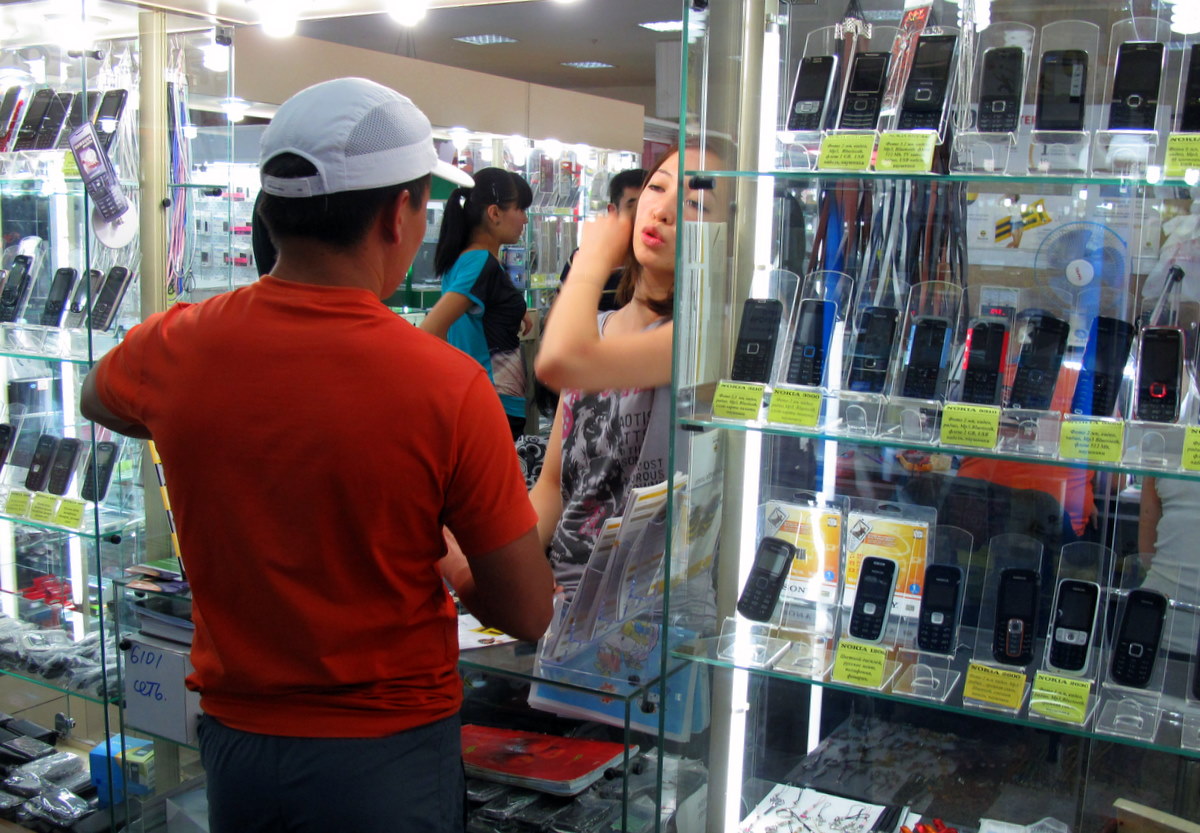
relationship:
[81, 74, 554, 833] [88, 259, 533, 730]
man wearing shirt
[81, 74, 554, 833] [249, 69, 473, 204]
man wearing hat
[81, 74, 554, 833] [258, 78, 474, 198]
man wearing cap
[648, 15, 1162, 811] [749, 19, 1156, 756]
case of phones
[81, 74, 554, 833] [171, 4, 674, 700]
man at window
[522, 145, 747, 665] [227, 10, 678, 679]
woman at window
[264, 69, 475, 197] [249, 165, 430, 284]
cap on head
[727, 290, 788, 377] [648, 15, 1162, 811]
phone in case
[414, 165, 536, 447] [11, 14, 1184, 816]
woman in store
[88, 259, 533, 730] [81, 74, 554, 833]
shirt on man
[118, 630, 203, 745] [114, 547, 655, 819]
box on counter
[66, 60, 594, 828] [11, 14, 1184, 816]
man standing in store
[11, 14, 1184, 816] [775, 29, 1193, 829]
store sells phones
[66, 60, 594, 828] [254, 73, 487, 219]
man wearing hat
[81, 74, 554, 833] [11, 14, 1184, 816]
man standing in store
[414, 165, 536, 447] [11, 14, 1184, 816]
woman standing in store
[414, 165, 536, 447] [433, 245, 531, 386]
woman wearing shirt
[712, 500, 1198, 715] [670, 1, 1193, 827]
phones in case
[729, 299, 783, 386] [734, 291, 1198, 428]
phone of phones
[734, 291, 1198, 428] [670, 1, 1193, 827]
phones in case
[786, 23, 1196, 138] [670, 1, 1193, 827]
phones in case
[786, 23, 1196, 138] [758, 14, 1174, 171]
phones in row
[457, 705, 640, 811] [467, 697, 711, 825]
book on shelf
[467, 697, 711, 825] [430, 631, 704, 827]
shelf in counter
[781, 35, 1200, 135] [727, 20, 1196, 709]
row of phones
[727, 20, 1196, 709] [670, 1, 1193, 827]
phones on display in case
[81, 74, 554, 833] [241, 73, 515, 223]
man wearing hat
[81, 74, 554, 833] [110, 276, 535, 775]
man wearing shirt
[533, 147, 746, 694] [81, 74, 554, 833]
woman talking to man